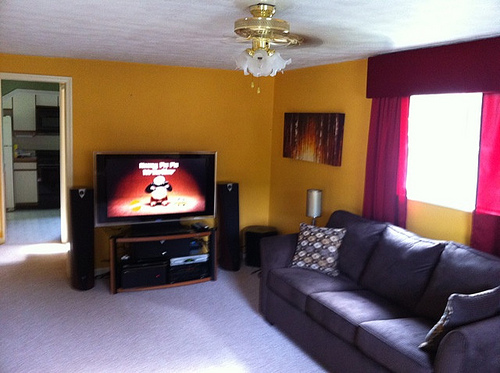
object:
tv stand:
[88, 143, 222, 297]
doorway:
[0, 70, 73, 253]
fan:
[206, 0, 306, 91]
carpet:
[1, 255, 336, 371]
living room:
[1, 0, 498, 371]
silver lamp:
[300, 186, 323, 218]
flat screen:
[93, 152, 216, 222]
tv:
[92, 145, 219, 224]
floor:
[12, 207, 39, 232]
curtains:
[358, 34, 498, 258]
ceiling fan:
[226, 4, 302, 95]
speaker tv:
[57, 143, 217, 296]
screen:
[86, 153, 208, 223]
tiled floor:
[23, 206, 54, 246]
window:
[398, 70, 480, 248]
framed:
[55, 162, 65, 274]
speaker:
[212, 182, 246, 268]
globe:
[227, 40, 297, 81]